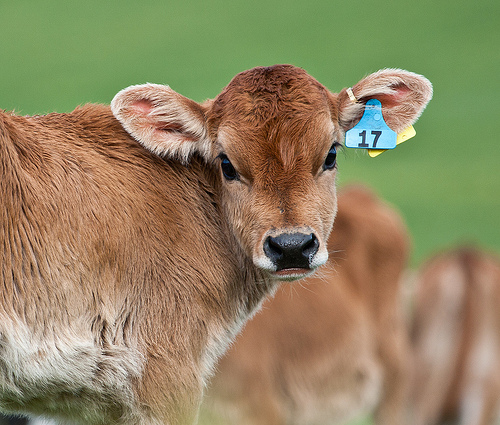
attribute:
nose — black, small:
[250, 231, 331, 272]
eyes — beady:
[213, 138, 341, 181]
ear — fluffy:
[338, 62, 436, 151]